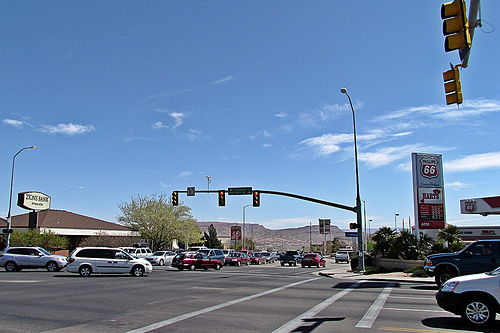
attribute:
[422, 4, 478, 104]
lights — two traffic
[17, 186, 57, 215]
sign — bank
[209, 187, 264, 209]
lights — two red stop 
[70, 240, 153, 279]
van — white , center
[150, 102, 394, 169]
clouds — wispy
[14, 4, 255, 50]
sky — blue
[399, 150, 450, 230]
sign — large red, white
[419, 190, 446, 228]
prices —  gas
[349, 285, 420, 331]
crosswalk —  pedestrian 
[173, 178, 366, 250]
light — street , stop 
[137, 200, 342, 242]
mountains — background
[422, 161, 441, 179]
number — 66, white colored 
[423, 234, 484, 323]
cars — stopped 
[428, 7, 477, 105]
light — traffic 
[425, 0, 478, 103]
light — traffic 